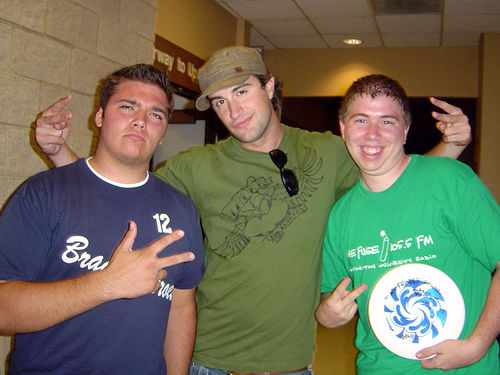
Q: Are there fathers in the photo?
A: No, there are no fathers.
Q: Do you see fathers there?
A: No, there are no fathers.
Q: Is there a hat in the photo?
A: Yes, there is a hat.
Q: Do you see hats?
A: Yes, there is a hat.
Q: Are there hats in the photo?
A: Yes, there is a hat.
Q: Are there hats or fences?
A: Yes, there is a hat.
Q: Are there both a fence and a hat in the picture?
A: No, there is a hat but no fences.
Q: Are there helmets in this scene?
A: No, there are no helmets.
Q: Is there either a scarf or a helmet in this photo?
A: No, there are no helmets or scarves.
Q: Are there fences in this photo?
A: No, there are no fences.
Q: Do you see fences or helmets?
A: No, there are no fences or helmets.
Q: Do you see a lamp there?
A: No, there are no lamps.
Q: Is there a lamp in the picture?
A: No, there are no lamps.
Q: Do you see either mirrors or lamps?
A: No, there are no lamps or mirrors.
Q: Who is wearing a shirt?
A: The boy is wearing a shirt.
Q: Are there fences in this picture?
A: No, there are no fences.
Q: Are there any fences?
A: No, there are no fences.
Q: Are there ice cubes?
A: No, there are no ice cubes.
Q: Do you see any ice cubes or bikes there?
A: No, there are no ice cubes or bikes.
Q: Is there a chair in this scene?
A: No, there are no chairs.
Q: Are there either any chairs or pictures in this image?
A: No, there are no chairs or pictures.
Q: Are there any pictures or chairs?
A: No, there are no chairs or pictures.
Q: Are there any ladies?
A: No, there are no ladies.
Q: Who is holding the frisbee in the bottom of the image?
A: The boy is holding the frisbee.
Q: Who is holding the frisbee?
A: The boy is holding the frisbee.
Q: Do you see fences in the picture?
A: No, there are no fences.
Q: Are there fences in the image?
A: No, there are no fences.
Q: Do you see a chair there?
A: No, there are no chairs.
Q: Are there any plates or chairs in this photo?
A: No, there are no chairs or plates.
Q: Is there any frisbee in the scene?
A: Yes, there is a frisbee.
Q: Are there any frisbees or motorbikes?
A: Yes, there is a frisbee.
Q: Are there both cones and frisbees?
A: No, there is a frisbee but no cones.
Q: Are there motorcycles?
A: No, there are no motorcycles.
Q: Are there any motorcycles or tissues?
A: No, there are no motorcycles or tissues.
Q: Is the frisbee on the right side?
A: Yes, the frisbee is on the right of the image.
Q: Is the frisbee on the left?
A: No, the frisbee is on the right of the image.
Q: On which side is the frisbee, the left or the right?
A: The frisbee is on the right of the image.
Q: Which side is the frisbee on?
A: The frisbee is on the right of the image.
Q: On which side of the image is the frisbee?
A: The frisbee is on the right of the image.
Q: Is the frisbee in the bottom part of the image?
A: Yes, the frisbee is in the bottom of the image.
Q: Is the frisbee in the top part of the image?
A: No, the frisbee is in the bottom of the image.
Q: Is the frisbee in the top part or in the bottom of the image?
A: The frisbee is in the bottom of the image.